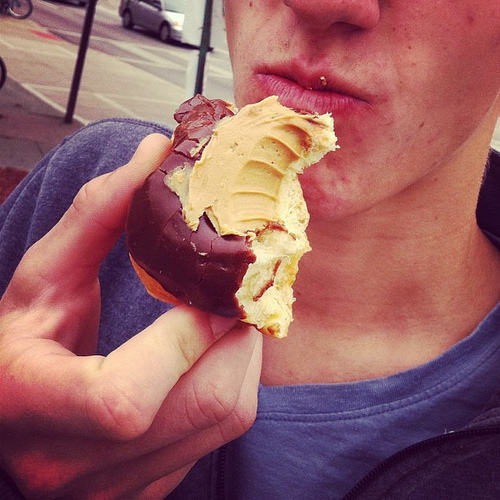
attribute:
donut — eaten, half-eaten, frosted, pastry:
[125, 94, 338, 336]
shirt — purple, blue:
[4, 115, 499, 495]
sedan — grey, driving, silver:
[119, 1, 207, 48]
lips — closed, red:
[252, 60, 369, 121]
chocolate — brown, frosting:
[124, 95, 246, 316]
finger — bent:
[51, 329, 251, 475]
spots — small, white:
[322, 76, 327, 88]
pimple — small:
[466, 15, 476, 29]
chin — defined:
[294, 161, 363, 216]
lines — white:
[24, 81, 129, 143]